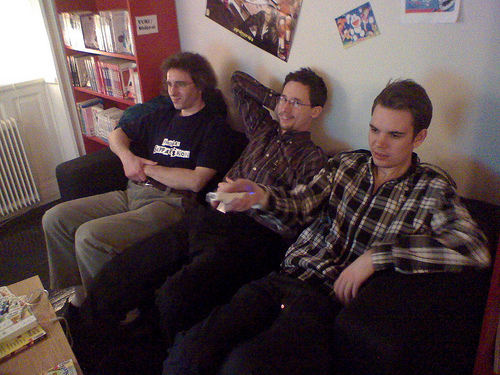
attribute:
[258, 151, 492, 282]
shirt — black, white, checkered, plaid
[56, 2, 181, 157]
bookshelf — in the corner, red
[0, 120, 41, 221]
radiator — white, mettalic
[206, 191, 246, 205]
remote controller — white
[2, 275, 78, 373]
coffee table — wooden, small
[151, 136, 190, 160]
writing — white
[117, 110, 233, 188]
t-shirt — black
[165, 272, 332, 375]
pants — black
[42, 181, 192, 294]
pants — brown, tan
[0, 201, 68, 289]
floor — carpeted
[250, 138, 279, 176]
buttons — white